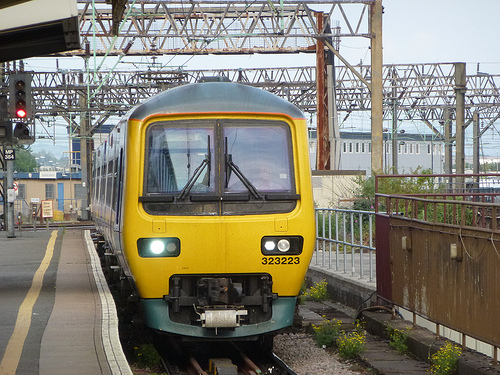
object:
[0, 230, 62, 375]
line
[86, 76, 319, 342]
train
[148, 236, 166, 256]
light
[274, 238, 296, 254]
light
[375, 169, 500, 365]
fence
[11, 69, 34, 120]
traffic signal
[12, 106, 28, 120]
light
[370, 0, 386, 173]
poles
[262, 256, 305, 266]
323223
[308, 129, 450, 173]
building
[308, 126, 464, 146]
roof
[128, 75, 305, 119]
green top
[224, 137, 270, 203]
windshield wipers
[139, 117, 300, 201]
windshield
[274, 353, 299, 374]
tracks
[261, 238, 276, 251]
lights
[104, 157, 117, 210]
window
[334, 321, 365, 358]
weeds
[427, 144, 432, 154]
windows